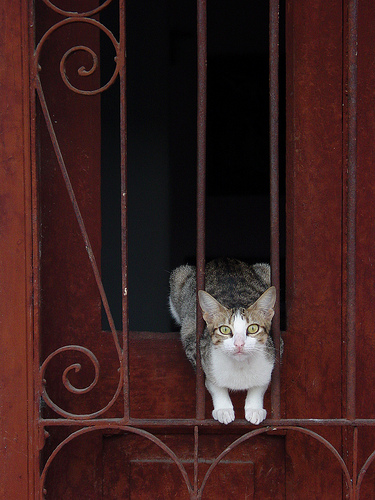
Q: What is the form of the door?
A: A spiral metal.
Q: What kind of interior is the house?
A: A dark interior.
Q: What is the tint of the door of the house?
A: Red.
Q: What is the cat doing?
A: Paying attention.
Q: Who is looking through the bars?
A: A cat.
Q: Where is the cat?
A: In a doorway.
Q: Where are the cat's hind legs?
A: Inside the doorway.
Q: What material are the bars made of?
A: Metal.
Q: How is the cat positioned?
A: Sitting.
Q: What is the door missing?
A: A panel.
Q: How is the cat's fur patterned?
A: Calico.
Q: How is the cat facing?
A: Forwards.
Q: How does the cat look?
A: Frightened.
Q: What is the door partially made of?
A: Metal.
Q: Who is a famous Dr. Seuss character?
A: The cat-in-the-hat.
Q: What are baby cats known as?
A: Kittens.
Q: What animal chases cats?
A: Dogs.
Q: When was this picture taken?
A: Day time.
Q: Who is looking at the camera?
A: The cat.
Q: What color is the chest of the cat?
A: White.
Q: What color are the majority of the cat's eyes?
A: Green.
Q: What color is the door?
A: Red.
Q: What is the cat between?
A: Metal bars.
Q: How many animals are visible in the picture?
A: One.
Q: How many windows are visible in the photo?
A: One.